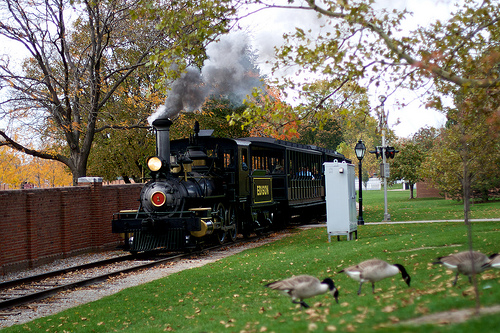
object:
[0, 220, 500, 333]
lawn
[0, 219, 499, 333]
space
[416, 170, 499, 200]
building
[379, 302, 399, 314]
leaves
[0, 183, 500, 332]
ground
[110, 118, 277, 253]
engine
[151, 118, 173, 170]
smoke stack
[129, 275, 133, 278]
gravel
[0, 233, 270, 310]
track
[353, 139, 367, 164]
light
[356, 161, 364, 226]
post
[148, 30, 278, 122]
steam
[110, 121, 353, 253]
train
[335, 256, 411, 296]
goose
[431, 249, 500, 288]
goose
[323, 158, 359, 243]
electrical box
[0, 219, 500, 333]
grass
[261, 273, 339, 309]
birds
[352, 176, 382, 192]
rail crossing